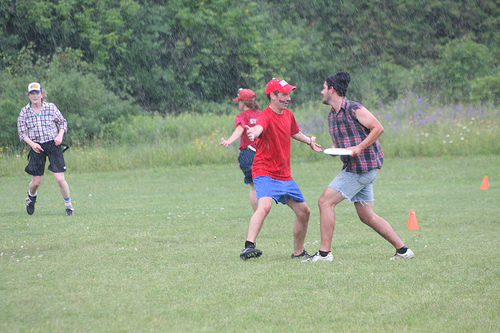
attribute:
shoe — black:
[239, 241, 264, 261]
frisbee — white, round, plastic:
[323, 143, 358, 157]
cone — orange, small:
[404, 203, 425, 234]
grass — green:
[3, 170, 497, 331]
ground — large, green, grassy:
[3, 133, 497, 332]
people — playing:
[17, 55, 420, 267]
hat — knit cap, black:
[326, 69, 352, 95]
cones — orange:
[399, 164, 494, 233]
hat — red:
[263, 78, 299, 94]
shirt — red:
[250, 104, 304, 181]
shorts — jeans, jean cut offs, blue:
[328, 162, 383, 205]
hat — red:
[232, 86, 254, 101]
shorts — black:
[22, 142, 67, 174]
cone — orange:
[479, 171, 492, 195]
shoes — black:
[241, 236, 310, 265]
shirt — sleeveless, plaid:
[325, 101, 385, 170]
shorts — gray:
[254, 173, 307, 203]